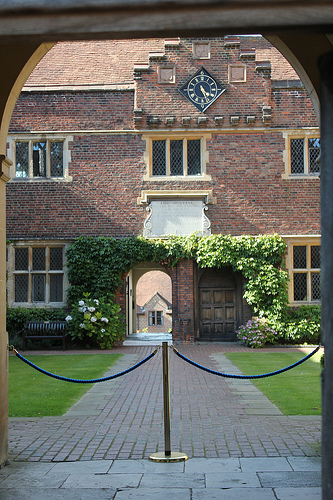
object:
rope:
[171, 343, 325, 380]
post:
[147, 340, 188, 462]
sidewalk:
[7, 345, 323, 461]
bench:
[20, 320, 67, 352]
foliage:
[65, 233, 290, 348]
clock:
[178, 65, 228, 115]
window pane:
[30, 139, 48, 179]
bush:
[234, 315, 277, 347]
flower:
[256, 331, 264, 337]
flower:
[87, 306, 95, 311]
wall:
[8, 36, 322, 346]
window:
[149, 138, 204, 178]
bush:
[67, 293, 125, 349]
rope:
[11, 345, 162, 384]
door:
[197, 264, 239, 342]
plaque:
[143, 199, 210, 238]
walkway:
[126, 262, 174, 345]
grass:
[223, 351, 324, 414]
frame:
[143, 130, 212, 182]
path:
[134, 326, 170, 341]